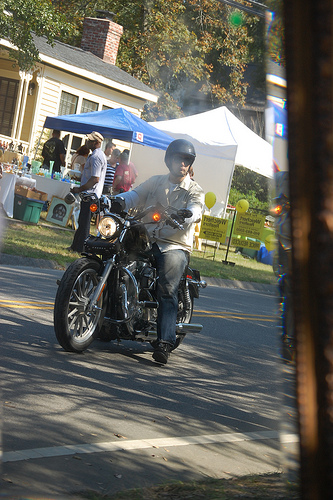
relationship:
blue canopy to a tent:
[43, 107, 176, 150] [26, 88, 190, 241]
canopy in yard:
[161, 99, 274, 172] [14, 106, 265, 254]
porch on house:
[0, 58, 40, 159] [0, 16, 161, 170]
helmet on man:
[164, 138, 194, 177] [95, 138, 205, 365]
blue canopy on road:
[43, 107, 176, 150] [11, 253, 277, 293]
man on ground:
[71, 131, 107, 248] [0, 215, 277, 500]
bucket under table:
[15, 196, 47, 223] [32, 174, 74, 211]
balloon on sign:
[202, 187, 261, 218] [130, 124, 164, 148]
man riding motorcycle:
[91, 137, 204, 364] [51, 179, 207, 364]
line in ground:
[2, 435, 266, 455] [0, 215, 277, 500]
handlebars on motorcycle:
[60, 181, 189, 235] [54, 191, 211, 353]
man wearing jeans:
[95, 138, 205, 365] [151, 250, 190, 346]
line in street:
[0, 299, 281, 322] [0, 262, 295, 389]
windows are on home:
[45, 89, 146, 159] [0, 8, 162, 179]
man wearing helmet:
[95, 138, 205, 365] [163, 137, 195, 166]